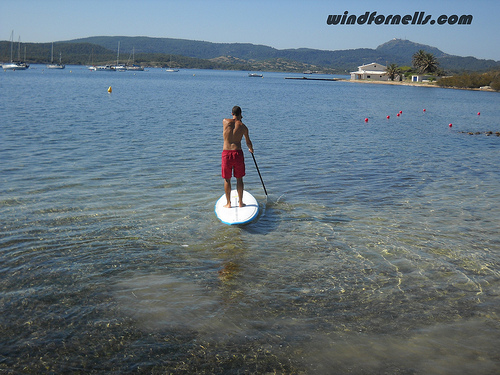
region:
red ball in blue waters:
[358, 110, 382, 135]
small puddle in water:
[106, 269, 250, 340]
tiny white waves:
[325, 263, 444, 292]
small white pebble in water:
[168, 232, 215, 267]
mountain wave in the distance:
[285, 32, 437, 52]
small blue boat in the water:
[238, 71, 271, 81]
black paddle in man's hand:
[248, 145, 295, 230]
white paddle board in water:
[208, 180, 274, 252]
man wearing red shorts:
[209, 149, 259, 180]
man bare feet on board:
[217, 194, 262, 216]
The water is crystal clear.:
[125, 162, 446, 353]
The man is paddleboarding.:
[205, 100, 285, 240]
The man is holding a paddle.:
[202, 91, 282, 226]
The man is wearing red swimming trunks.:
[210, 145, 251, 185]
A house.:
[345, 60, 390, 90]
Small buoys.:
[352, 95, 492, 156]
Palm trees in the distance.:
[390, 41, 435, 86]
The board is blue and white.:
[195, 180, 275, 235]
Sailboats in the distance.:
[5, 30, 155, 90]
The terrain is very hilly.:
[60, 30, 327, 72]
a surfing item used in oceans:
[212, 187, 262, 229]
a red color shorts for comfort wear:
[217, 144, 247, 188]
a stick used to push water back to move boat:
[244, 153, 279, 200]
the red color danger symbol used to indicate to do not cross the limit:
[356, 100, 491, 155]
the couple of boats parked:
[86, 46, 146, 83]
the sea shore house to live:
[347, 58, 397, 92]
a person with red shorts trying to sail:
[191, 89, 298, 259]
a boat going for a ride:
[243, 69, 274, 98]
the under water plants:
[24, 205, 256, 365]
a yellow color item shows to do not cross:
[90, 83, 122, 100]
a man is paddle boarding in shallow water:
[215, 105, 270, 224]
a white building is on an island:
[350, 60, 390, 82]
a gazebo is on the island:
[410, 73, 418, 82]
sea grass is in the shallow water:
[0, 197, 497, 373]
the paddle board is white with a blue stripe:
[215, 188, 259, 224]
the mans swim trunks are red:
[220, 149, 245, 179]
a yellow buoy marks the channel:
[107, 87, 114, 95]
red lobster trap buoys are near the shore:
[362, 116, 369, 123]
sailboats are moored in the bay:
[0, 30, 25, 69]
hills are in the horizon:
[0, 35, 497, 73]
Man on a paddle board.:
[212, 102, 272, 226]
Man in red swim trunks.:
[212, 99, 272, 227]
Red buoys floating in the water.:
[363, 104, 488, 146]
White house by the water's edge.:
[349, 59, 394, 83]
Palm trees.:
[389, 46, 437, 83]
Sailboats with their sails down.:
[2, 28, 187, 75]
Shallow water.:
[0, 226, 492, 374]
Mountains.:
[2, 33, 497, 73]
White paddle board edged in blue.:
[211, 184, 260, 228]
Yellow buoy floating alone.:
[101, 83, 114, 95]